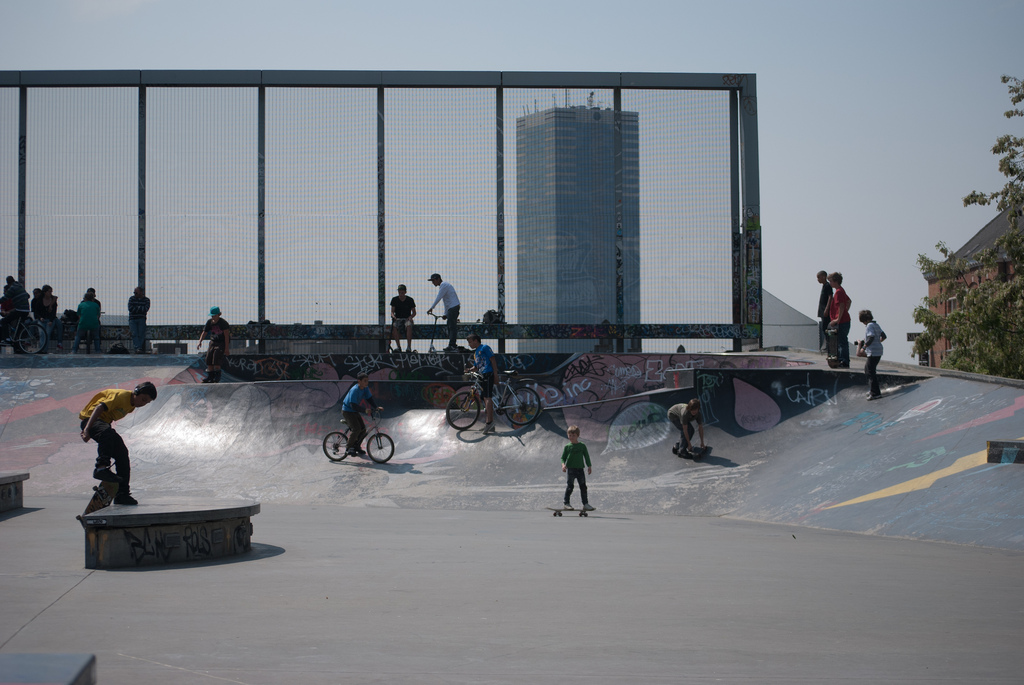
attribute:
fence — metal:
[2, 132, 776, 368]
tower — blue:
[507, 141, 657, 364]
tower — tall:
[501, 207, 653, 385]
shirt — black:
[373, 287, 426, 333]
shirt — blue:
[349, 366, 373, 425]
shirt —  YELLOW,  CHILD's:
[85, 386, 133, 423]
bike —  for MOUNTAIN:
[443, 365, 543, 432]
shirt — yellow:
[84, 373, 126, 425]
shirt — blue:
[343, 378, 365, 418]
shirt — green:
[557, 445, 583, 458]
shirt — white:
[436, 287, 456, 354]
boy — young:
[523, 414, 604, 598]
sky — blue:
[20, 110, 1012, 342]